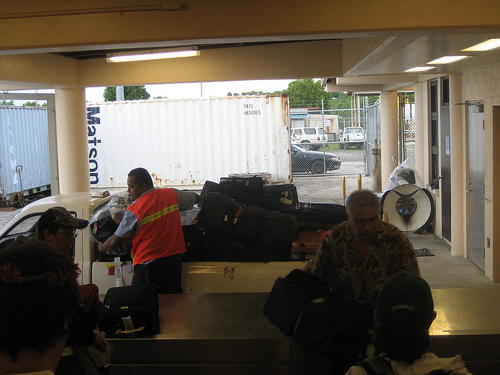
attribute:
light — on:
[102, 42, 203, 66]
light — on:
[401, 58, 435, 82]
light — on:
[424, 50, 471, 71]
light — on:
[455, 32, 497, 56]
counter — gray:
[91, 283, 497, 355]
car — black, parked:
[290, 142, 342, 176]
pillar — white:
[449, 74, 465, 258]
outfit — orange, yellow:
[118, 188, 188, 266]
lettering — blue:
[80, 101, 117, 194]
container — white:
[87, 102, 322, 194]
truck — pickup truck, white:
[3, 191, 315, 291]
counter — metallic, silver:
[92, 347, 346, 366]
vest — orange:
[127, 187, 187, 266]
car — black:
[289, 144, 343, 179]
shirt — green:
[275, 160, 437, 302]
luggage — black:
[194, 174, 308, 269]